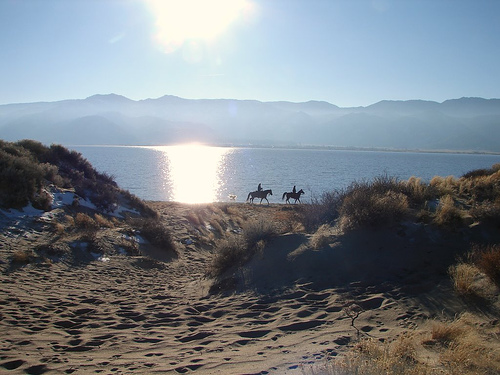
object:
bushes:
[1, 132, 26, 159]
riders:
[278, 183, 303, 206]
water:
[22, 135, 499, 210]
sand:
[32, 260, 397, 373]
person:
[254, 181, 264, 191]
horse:
[279, 190, 306, 202]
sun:
[150, 2, 261, 47]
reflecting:
[157, 143, 237, 204]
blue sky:
[264, 2, 499, 86]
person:
[291, 184, 297, 194]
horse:
[241, 188, 272, 203]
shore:
[17, 125, 497, 252]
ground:
[3, 195, 496, 373]